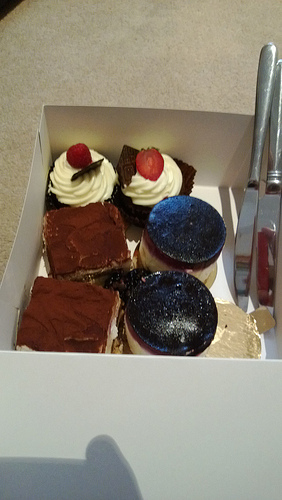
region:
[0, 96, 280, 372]
A box of baked goodies.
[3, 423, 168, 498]
A shadow on a bakery box.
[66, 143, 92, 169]
Strawberry on top of a cupcake.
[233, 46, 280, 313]
Two brand new shiney butter knives.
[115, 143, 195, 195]
Chocolate brownie with white cream.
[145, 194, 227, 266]
A purple jelly roll in a box.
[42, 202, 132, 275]
A slice of yellow and choclate cake.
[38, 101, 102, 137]
The corner of a cake box.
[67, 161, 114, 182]
A piece of chocolate candy.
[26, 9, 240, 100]
A white formica tabletop.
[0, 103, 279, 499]
box filled with pastries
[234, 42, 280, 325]
two knives in the box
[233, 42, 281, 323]
silver knives used for cutting the cakes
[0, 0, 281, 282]
marble counter with box of pastries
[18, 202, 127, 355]
two square pieces of chocolate cake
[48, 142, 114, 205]
circular cupcake with white icing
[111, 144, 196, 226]
square piece of cupcake with white icing on it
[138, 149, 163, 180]
half of strawberry on cupcake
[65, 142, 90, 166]
whole strawberry on cupcake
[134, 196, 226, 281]
circular cake with blueberry top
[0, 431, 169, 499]
shadow on pastry box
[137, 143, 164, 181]
ripe red strawberry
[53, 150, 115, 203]
whirl of whipped cream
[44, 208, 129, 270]
layer of milk chocolate frosting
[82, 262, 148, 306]
blackberries on bottom of box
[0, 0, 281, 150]
ecru colored carpet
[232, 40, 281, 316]
two stainless steel butter knives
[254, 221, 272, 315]
reflection of red in knife blade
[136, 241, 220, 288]
creamy filling in center of pastry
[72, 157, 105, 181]
thin chocolate wafer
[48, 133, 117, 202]
cupcake with white frosting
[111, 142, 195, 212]
cupcake with chocolate and white frosting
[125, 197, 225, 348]
two desserts with dark blue tops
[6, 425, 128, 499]
shadown on side of white box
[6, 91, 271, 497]
white box holding desserts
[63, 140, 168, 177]
red berries on top of two cupcakes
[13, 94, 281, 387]
box holding six desserts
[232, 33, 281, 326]
two knives propped on box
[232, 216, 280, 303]
reflection on two knives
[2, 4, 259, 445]
countertop white box is sitting on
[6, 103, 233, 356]
six pastries in a white box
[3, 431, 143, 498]
shadow on outside of white box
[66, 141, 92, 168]
red raspberry on top of cupcake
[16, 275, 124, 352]
square piece of chocolate dessert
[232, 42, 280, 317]
two butter knives in the pastry box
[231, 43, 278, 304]
butter knives in box are silver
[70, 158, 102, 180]
decorative chocolate wafer on cupcake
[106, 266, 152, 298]
blackberries in between pastries in box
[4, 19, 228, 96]
thin white carpet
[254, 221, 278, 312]
reflection on silver knife